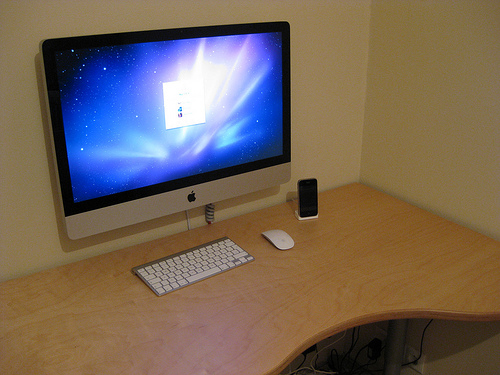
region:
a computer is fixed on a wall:
[29, 17, 301, 254]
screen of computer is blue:
[28, 15, 298, 226]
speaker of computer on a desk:
[289, 169, 329, 230]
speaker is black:
[293, 170, 325, 227]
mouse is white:
[256, 220, 307, 260]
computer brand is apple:
[22, 6, 296, 243]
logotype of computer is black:
[173, 175, 215, 217]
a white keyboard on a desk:
[126, 227, 263, 302]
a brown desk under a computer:
[0, 173, 497, 372]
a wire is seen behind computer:
[194, 199, 221, 233]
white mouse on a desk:
[256, 214, 298, 257]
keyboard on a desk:
[120, 228, 257, 316]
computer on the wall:
[33, 11, 313, 261]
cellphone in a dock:
[288, 171, 321, 229]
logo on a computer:
[180, 186, 199, 211]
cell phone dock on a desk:
[292, 206, 322, 222]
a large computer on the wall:
[41, 3, 308, 255]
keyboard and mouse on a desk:
[118, 212, 303, 313]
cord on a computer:
[198, 194, 220, 231]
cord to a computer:
[177, 203, 194, 235]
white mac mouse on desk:
[256, 222, 298, 254]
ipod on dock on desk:
[291, 173, 339, 231]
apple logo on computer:
[183, 187, 201, 211]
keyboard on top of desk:
[118, 229, 272, 301]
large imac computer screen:
[22, 8, 286, 206]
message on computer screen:
[137, 71, 229, 142]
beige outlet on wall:
[393, 345, 442, 370]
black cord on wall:
[408, 326, 438, 359]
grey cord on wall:
[178, 213, 199, 226]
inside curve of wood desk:
[285, 297, 492, 339]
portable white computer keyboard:
[121, 232, 265, 294]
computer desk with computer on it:
[23, 241, 483, 374]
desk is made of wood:
[23, 256, 443, 372]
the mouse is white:
[252, 219, 306, 266]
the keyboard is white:
[129, 240, 324, 283]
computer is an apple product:
[28, 36, 372, 241]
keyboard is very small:
[122, 247, 286, 309]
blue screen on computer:
[89, 61, 284, 141]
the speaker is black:
[293, 161, 355, 253]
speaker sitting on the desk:
[285, 167, 335, 248]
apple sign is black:
[171, 179, 216, 219]